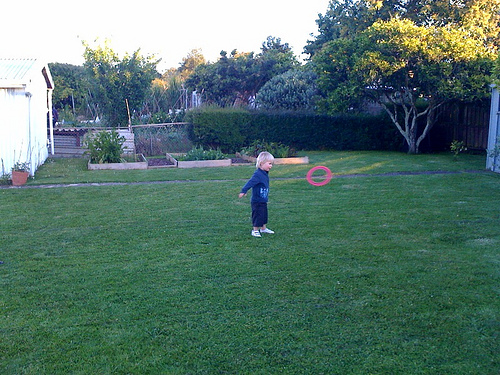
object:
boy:
[237, 152, 276, 238]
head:
[256, 151, 276, 171]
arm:
[239, 170, 262, 198]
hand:
[239, 192, 247, 199]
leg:
[251, 199, 266, 239]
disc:
[305, 164, 331, 187]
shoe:
[250, 229, 261, 237]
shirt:
[240, 167, 270, 203]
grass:
[6, 146, 498, 373]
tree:
[301, 16, 499, 154]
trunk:
[377, 87, 447, 153]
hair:
[255, 151, 275, 168]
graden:
[49, 55, 312, 167]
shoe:
[260, 227, 274, 234]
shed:
[0, 58, 55, 179]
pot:
[11, 171, 32, 185]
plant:
[10, 159, 32, 174]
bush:
[188, 105, 403, 153]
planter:
[87, 153, 148, 169]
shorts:
[250, 198, 268, 228]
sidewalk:
[0, 169, 494, 187]